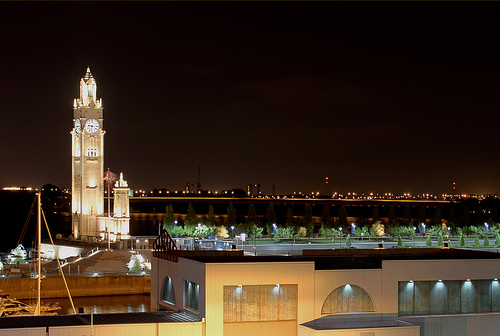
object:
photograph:
[3, 0, 499, 334]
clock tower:
[69, 67, 105, 240]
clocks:
[84, 119, 99, 134]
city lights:
[0, 180, 496, 228]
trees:
[482, 232, 491, 246]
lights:
[490, 280, 500, 293]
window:
[320, 283, 374, 314]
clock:
[85, 118, 100, 134]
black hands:
[88, 125, 94, 128]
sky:
[2, 0, 498, 192]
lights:
[129, 191, 469, 208]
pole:
[37, 189, 40, 316]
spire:
[86, 64, 93, 76]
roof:
[151, 248, 499, 270]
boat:
[0, 297, 63, 317]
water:
[20, 294, 152, 315]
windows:
[223, 284, 297, 322]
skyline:
[3, 165, 499, 198]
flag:
[104, 170, 119, 188]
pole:
[107, 165, 111, 247]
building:
[56, 226, 145, 250]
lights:
[453, 182, 456, 188]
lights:
[325, 177, 328, 180]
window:
[159, 276, 175, 306]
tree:
[162, 204, 186, 236]